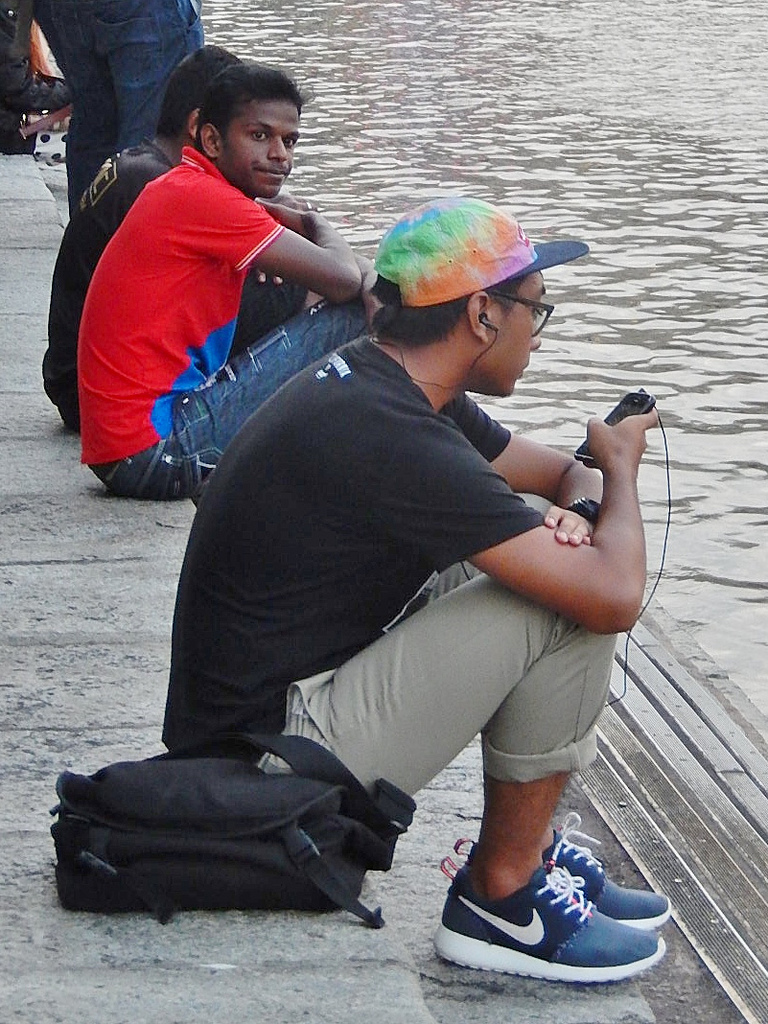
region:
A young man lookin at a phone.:
[151, 196, 676, 983]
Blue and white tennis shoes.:
[438, 835, 682, 983]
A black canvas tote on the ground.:
[49, 721, 414, 922]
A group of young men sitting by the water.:
[49, 47, 687, 983]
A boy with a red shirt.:
[73, 57, 364, 472]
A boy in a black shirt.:
[164, 227, 591, 759]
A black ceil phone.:
[575, 388, 668, 471]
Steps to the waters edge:
[597, 561, 762, 994]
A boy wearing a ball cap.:
[155, 193, 687, 982]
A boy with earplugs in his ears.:
[166, 197, 687, 981]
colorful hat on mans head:
[360, 190, 589, 309]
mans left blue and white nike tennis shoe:
[431, 849, 666, 990]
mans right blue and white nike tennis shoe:
[479, 823, 673, 928]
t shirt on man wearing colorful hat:
[154, 327, 554, 760]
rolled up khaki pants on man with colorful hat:
[247, 491, 618, 802]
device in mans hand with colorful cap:
[570, 392, 657, 463]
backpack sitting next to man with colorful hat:
[44, 723, 418, 932]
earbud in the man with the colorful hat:
[359, 309, 501, 392]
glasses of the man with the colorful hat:
[482, 285, 557, 336]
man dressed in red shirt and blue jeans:
[70, 54, 383, 492]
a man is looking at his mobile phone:
[373, 183, 674, 493]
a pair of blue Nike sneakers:
[436, 809, 675, 997]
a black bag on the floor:
[21, 717, 410, 967]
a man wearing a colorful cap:
[374, 194, 580, 415]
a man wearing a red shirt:
[121, 54, 391, 502]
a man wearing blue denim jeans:
[72, 24, 375, 506]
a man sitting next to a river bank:
[121, 200, 765, 977]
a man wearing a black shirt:
[169, 184, 612, 758]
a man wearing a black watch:
[354, 183, 618, 556]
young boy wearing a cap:
[156, 193, 672, 987]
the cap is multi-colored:
[372, 193, 594, 316]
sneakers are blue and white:
[429, 825, 678, 996]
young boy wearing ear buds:
[160, 195, 676, 967]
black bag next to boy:
[49, 726, 422, 931]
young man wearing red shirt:
[75, 58, 396, 506]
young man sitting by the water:
[148, 194, 691, 979]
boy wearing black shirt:
[165, 200, 677, 982]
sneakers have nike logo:
[429, 837, 675, 989]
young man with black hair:
[77, 61, 382, 513]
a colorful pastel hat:
[377, 188, 597, 299]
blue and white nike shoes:
[435, 820, 677, 976]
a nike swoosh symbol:
[454, 884, 557, 952]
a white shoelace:
[538, 864, 597, 926]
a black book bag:
[53, 746, 409, 928]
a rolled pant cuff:
[481, 742, 604, 786]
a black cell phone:
[577, 385, 653, 463]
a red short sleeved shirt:
[82, 152, 281, 467]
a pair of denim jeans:
[32, 0, 218, 418]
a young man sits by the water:
[177, 195, 677, 984]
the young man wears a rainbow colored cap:
[369, 196, 590, 309]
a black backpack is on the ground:
[48, 728, 399, 933]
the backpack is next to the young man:
[39, 734, 404, 933]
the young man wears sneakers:
[434, 825, 669, 988]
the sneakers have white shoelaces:
[548, 809, 602, 917]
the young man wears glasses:
[485, 285, 554, 335]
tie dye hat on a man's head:
[370, 188, 592, 315]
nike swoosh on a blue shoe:
[449, 890, 553, 953]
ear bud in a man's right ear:
[477, 305, 501, 337]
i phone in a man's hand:
[573, 381, 658, 469]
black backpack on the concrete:
[46, 730, 432, 935]